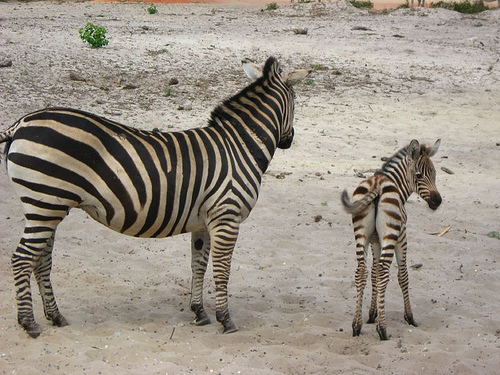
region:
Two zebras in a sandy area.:
[1, 52, 451, 339]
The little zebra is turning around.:
[340, 136, 445, 338]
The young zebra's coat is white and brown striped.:
[337, 135, 447, 343]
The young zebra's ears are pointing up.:
[405, 135, 445, 156]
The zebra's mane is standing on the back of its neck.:
[205, 55, 281, 126]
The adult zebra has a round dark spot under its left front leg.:
[190, 233, 201, 254]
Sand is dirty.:
[5, 0, 496, 91]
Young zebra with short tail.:
[340, 181, 382, 214]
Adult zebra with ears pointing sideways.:
[235, 53, 313, 89]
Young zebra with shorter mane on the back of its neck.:
[378, 146, 412, 171]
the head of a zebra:
[231, 48, 375, 168]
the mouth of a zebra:
[267, 95, 327, 175]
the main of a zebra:
[191, 54, 303, 145]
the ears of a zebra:
[197, 25, 321, 137]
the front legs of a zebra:
[179, 189, 264, 326]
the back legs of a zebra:
[14, 185, 104, 336]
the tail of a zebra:
[331, 169, 407, 269]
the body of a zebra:
[31, 72, 296, 285]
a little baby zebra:
[320, 83, 495, 313]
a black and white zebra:
[29, 77, 334, 294]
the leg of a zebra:
[211, 225, 239, 327]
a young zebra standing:
[344, 136, 440, 341]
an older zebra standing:
[6, 56, 294, 332]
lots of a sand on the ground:
[259, 204, 344, 359]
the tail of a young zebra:
[339, 188, 379, 211]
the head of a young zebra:
[407, 132, 449, 208]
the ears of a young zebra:
[399, 138, 444, 152]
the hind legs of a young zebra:
[348, 236, 395, 343]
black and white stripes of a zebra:
[43, 118, 215, 214]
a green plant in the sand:
[81, 21, 108, 46]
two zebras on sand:
[25, 59, 464, 344]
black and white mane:
[205, 63, 269, 123]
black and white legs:
[8, 211, 247, 341]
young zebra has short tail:
[358, 173, 397, 240]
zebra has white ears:
[231, 50, 334, 103]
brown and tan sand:
[160, 59, 430, 184]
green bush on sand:
[67, 16, 133, 86]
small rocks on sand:
[7, 43, 325, 143]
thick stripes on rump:
[32, 113, 135, 223]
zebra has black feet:
[162, 289, 247, 366]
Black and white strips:
[105, 143, 178, 209]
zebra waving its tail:
[340, 185, 375, 210]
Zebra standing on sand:
[181, 300, 261, 346]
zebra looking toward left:
[240, 55, 300, 150]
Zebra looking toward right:
[406, 140, 438, 207]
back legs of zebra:
[10, 200, 65, 335]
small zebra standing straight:
[340, 140, 440, 340]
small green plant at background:
[75, 15, 105, 41]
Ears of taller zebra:
[240, 60, 305, 80]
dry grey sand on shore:
[111, 331, 218, 371]